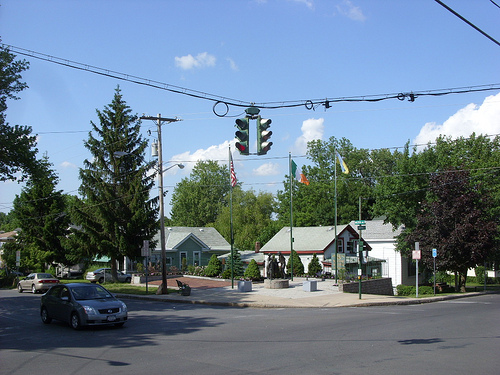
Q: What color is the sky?
A: Blue.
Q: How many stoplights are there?
A: 2.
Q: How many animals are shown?
A: 0.